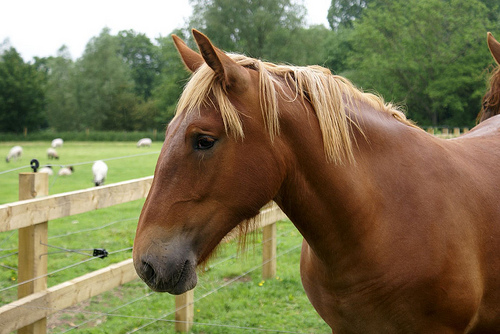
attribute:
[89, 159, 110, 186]
sheep — white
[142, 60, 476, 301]
horse — brown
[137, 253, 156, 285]
nostril — horse's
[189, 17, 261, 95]
ear — horse's, brown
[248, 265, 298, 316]
dandelions — yellow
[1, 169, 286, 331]
fence — wood, wooden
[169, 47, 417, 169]
mane — horse's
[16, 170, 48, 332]
post — wooden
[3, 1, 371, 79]
sky — bright, patch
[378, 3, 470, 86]
trees — in background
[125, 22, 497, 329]
horse — brown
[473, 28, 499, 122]
horse — brown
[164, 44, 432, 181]
mane — long, tan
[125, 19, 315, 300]
head — large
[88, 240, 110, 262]
clip — black